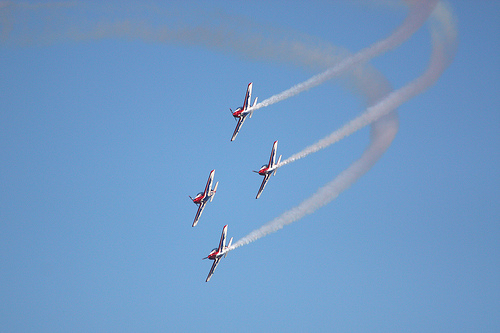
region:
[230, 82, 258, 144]
Plane flying in sky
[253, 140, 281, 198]
Plane flying in sky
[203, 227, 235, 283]
Plane flying in sky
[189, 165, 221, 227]
Plane flying in sky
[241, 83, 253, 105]
wing on an airplane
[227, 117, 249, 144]
wing on an airplane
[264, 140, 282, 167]
wing on an airplane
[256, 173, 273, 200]
wing on an airplane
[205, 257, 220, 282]
wing on an airplane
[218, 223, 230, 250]
wing on an airplane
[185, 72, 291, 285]
Airplanes in close formation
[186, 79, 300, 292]
Stunt pilots performing aerial moves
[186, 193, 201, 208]
Propeller on stunt airplane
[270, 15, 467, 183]
Vapor trail of stunt airplane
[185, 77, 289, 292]
Formation of airplanes banking right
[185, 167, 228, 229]
Lead airplane of stunt team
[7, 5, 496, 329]
Cloudless blue sky for aerial performance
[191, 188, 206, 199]
Cockpit of stunt airplane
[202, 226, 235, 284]
Underside of stunt airplane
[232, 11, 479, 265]
Vapor trails of three stunt airplanes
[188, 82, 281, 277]
Airplanes in the sky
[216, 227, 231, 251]
The left wing of the airplane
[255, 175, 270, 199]
The right wing of the airplane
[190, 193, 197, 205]
The propellor of the airplane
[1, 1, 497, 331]
Blue sky above the airplanes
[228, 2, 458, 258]
Smoke trailing behind the airplanes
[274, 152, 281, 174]
The tail of the airpalne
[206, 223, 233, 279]
The airplane is flying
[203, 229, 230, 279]
The airplane is trailing smoke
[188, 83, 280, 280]
The airplanes are flying in a group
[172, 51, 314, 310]
four jet planes in the sky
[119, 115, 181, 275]
the sky is clear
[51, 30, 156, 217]
the sky is clear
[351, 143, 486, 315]
the sky is clear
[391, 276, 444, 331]
the sky is clear